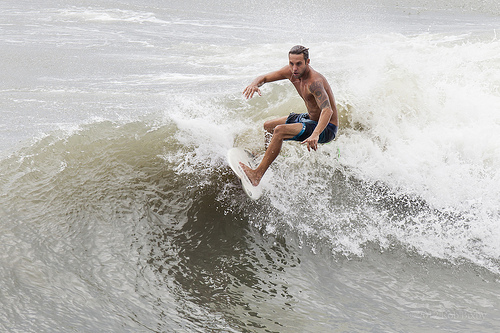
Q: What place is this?
A: It is an ocean.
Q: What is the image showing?
A: It is showing an ocean.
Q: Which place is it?
A: It is an ocean.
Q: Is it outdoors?
A: Yes, it is outdoors.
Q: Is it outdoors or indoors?
A: It is outdoors.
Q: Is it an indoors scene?
A: No, it is outdoors.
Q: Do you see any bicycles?
A: No, there are no bicycles.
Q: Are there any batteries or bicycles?
A: No, there are no bicycles or batteries.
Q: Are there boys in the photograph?
A: No, there are no boys.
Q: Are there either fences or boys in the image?
A: No, there are no boys or fences.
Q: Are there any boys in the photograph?
A: No, there are no boys.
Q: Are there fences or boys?
A: No, there are no boys or fences.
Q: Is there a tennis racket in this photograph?
A: No, there are no rackets.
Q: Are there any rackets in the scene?
A: No, there are no rackets.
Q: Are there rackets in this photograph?
A: No, there are no rackets.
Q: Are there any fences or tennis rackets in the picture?
A: No, there are no tennis rackets or fences.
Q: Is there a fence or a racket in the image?
A: No, there are no rackets or fences.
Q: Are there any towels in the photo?
A: No, there are no towels.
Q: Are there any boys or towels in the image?
A: No, there are no towels or boys.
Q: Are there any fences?
A: No, there are no fences.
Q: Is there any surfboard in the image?
A: Yes, there is a surfboard.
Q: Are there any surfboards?
A: Yes, there is a surfboard.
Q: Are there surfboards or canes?
A: Yes, there is a surfboard.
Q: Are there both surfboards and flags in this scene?
A: No, there is a surfboard but no flags.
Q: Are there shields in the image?
A: No, there are no shields.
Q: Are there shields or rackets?
A: No, there are no shields or rackets.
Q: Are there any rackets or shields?
A: No, there are no shields or rackets.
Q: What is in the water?
A: The surfboard is in the water.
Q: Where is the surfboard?
A: The surfboard is in the water.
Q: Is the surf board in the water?
A: Yes, the surf board is in the water.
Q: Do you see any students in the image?
A: No, there are no students.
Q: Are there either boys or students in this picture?
A: No, there are no students or boys.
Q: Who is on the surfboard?
A: The man is on the surfboard.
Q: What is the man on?
A: The man is on the surfboard.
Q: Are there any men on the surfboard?
A: Yes, there is a man on the surfboard.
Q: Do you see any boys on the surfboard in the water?
A: No, there is a man on the surf board.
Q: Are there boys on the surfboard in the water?
A: No, there is a man on the surf board.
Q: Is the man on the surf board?
A: Yes, the man is on the surf board.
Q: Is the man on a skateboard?
A: No, the man is on the surf board.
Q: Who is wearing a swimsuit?
A: The man is wearing a swimsuit.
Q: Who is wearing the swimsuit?
A: The man is wearing a swimsuit.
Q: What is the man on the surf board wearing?
A: The man is wearing a swimsuit.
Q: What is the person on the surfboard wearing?
A: The man is wearing a swimsuit.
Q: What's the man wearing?
A: The man is wearing a swimsuit.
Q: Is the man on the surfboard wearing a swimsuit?
A: Yes, the man is wearing a swimsuit.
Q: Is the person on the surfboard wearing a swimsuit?
A: Yes, the man is wearing a swimsuit.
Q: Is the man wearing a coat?
A: No, the man is wearing a swimsuit.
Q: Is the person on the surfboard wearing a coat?
A: No, the man is wearing a swimsuit.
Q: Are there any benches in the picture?
A: No, there are no benches.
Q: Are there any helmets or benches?
A: No, there are no benches or helmets.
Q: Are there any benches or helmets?
A: No, there are no benches or helmets.